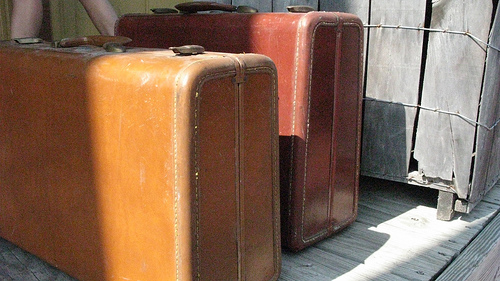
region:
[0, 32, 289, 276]
a brown piece of luggage.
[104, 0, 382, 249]
a red piece of luggage.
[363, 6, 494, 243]
a piece of rotten luggage.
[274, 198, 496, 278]
a section of the floor.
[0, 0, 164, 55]
a section of luggage.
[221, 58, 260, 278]
a seam in the side of luggage.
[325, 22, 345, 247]
a slit in the side of luggage.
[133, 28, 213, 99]
a latch on a piece of luggage.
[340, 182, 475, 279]
sunlight shining on the ground.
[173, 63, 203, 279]
thread on luggage.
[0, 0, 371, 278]
two old leather suitcases [i own at least one exactly the same myself]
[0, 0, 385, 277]
suitcases are heavy, sturdy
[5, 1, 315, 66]
both suitcases have bronze appointments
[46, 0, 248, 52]
short, sturdy handles on both suitcases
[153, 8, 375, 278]
stitched seams down, & beside, the sides of both suitcases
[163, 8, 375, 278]
stitching is detail stitching, of a lighter colour than the leather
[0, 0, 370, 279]
suitcases are -@ least- half a century old, more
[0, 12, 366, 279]
little scrapes+small bruises on golden brown suitcase & red brown suitcase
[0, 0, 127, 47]
someone's leg+someone's arm, impossible to tell whose, or anything else about them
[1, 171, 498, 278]
suitcases sit on tightly fitted, well jointed slats [i cant tell what kind of joint, apologies]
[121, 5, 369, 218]
Two suitcases stand next to each other.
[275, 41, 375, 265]
The right suitcase is crooked.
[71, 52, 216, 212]
The left suitcase is light brown.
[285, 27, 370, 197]
The right suit case is dark brown.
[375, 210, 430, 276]
The floor is pale grey wood.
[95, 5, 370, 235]
The right suitcase is the taller of the two.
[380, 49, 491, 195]
A wooden box is beside the suitcases.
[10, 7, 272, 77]
The suitcases are partly shaded.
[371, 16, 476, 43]
The wooden box is covered in metal wire.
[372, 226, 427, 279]
The wood floor is peeling.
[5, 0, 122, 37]
slim brown feet of a woman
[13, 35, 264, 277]
Orange briefcase with a silver handle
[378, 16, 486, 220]
An old wooden box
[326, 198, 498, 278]
A wooden stand holding boxes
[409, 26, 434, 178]
space in the wooden old Box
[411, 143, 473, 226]
Broken part of a wooden box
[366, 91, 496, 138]
String tied around a box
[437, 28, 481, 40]
Nails pinning the a string areound a wooden box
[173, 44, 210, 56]
A silver opener of a briefcase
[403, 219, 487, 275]
Nails used on the wooden stand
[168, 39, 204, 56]
faded clasp on suitcase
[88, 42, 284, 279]
sun shining on half of suitcase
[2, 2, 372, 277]
two, dusty brown suitcases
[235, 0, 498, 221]
crate made from pallet wood and wire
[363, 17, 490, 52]
rusted wire clips on wood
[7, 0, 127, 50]
person's calf and arm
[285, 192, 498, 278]
faded wood decking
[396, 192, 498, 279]
screws drilled into old decking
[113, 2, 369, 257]
tall brown suitcase on deck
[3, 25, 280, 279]
light brown old suitcase